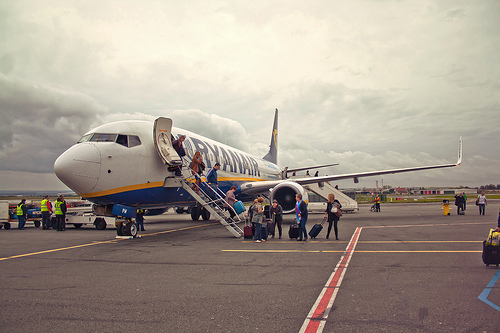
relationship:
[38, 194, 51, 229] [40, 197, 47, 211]
man wearing vest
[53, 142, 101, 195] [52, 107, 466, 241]
nose of plane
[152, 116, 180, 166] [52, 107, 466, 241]
door of plane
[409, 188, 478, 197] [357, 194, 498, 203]
building beyond grass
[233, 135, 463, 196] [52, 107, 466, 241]
wing of plane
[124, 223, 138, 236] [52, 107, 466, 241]
wheel of plane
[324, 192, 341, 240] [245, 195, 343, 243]
person in group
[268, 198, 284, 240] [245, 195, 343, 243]
person in group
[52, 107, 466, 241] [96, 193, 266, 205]
plane has belly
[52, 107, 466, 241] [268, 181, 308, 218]
plane has engine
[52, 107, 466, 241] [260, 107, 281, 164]
plane has tail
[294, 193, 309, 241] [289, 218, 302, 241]
person carrying bag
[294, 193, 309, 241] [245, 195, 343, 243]
person in group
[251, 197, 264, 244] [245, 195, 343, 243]
person in group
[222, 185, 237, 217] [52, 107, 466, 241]
person leaving plane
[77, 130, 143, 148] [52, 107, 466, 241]
windshield of plane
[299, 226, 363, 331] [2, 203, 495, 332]
line on tarmac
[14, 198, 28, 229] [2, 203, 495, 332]
worker on tarmac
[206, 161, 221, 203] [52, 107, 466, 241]
person leaving plane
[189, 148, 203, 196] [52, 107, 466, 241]
woman walking out of plane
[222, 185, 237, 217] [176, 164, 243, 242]
person walking down stairs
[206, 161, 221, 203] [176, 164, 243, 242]
person walking down stairs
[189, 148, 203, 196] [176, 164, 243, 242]
woman walking down stairs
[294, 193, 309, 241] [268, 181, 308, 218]
person in front of engine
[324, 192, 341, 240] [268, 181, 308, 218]
person in front of engine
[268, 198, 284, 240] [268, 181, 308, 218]
person in front of engine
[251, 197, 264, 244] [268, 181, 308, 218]
person in front of engine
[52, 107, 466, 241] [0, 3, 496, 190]
plane in front of clouds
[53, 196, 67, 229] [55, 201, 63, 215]
worker wearing vest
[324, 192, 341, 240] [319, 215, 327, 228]
person holding handle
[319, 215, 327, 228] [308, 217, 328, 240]
handle of luggage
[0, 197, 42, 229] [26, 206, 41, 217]
cart for luggage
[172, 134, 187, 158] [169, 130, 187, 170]
person walking through doorway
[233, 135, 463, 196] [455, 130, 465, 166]
wing has tip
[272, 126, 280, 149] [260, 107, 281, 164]
logo on tail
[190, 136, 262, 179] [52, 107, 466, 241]
ryanair on plane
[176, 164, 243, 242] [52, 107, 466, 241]
stairs lead up to plane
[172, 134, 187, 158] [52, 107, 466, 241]
person exiting plane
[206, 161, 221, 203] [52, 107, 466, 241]
person exiting plane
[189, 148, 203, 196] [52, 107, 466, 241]
woman exiting plane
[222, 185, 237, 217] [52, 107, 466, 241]
person exiting plane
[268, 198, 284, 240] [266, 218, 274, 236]
person grabs luggage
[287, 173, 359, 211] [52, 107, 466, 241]
ramp back of plane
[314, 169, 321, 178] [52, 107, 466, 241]
passenger exiting plane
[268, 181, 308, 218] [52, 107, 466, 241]
engine on plane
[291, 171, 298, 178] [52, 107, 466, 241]
passenger exiting plane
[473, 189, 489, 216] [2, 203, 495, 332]
man on tarmac